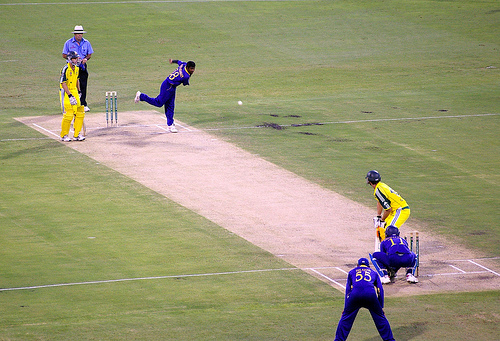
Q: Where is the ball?
A: In the air.